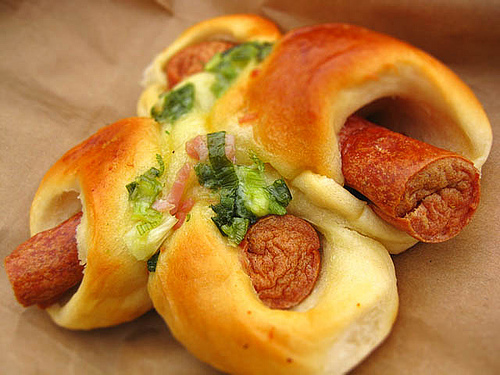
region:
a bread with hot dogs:
[7, 6, 491, 372]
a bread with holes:
[5, 0, 490, 370]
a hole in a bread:
[311, 58, 488, 255]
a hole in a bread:
[231, 198, 339, 325]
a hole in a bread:
[5, 182, 99, 329]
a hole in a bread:
[132, 20, 253, 84]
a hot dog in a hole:
[333, 81, 483, 243]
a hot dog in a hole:
[231, 202, 328, 322]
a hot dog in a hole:
[3, 195, 90, 316]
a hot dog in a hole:
[136, 19, 238, 84]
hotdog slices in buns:
[13, 1, 495, 373]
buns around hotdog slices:
[29, 11, 485, 361]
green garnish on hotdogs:
[128, 47, 270, 233]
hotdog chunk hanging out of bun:
[340, 123, 479, 232]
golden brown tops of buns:
[51, 10, 380, 204]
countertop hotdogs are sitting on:
[8, 10, 498, 373]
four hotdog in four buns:
[11, 13, 488, 373]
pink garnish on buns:
[157, 134, 236, 226]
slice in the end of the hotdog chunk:
[402, 180, 462, 214]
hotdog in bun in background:
[128, 10, 278, 112]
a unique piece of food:
[27, 12, 479, 369]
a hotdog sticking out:
[296, 96, 498, 251]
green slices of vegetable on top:
[85, 121, 295, 236]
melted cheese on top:
[98, 67, 290, 233]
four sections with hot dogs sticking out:
[69, 11, 471, 360]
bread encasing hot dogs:
[31, 26, 481, 373]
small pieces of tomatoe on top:
[137, 131, 239, 218]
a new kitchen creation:
[14, 17, 493, 366]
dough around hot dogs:
[27, 27, 470, 374]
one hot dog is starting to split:
[350, 148, 490, 245]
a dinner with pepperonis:
[11, 15, 491, 370]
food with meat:
[15, 50, 490, 365]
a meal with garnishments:
[15, 50, 470, 360]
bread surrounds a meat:
[245, 30, 490, 245]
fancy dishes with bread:
[5, 50, 485, 370]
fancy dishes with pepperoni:
[15, 15, 495, 370]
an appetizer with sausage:
[0, 10, 495, 365]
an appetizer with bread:
[10, 15, 490, 365]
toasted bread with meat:
[240, 20, 490, 250]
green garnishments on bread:
[106, 122, 401, 372]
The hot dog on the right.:
[328, 126, 476, 239]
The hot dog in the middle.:
[245, 220, 320, 305]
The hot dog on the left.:
[5, 220, 85, 300]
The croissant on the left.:
[32, 152, 147, 324]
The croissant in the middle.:
[147, 189, 397, 374]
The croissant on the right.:
[252, 25, 499, 245]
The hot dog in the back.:
[171, 48, 222, 66]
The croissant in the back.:
[138, 12, 268, 99]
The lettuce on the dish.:
[145, 61, 285, 254]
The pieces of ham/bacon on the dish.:
[156, 126, 232, 230]